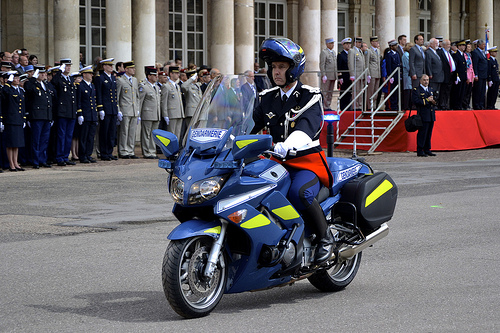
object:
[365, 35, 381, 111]
people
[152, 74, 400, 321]
bike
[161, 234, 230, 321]
wheels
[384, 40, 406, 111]
people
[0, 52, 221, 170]
crowd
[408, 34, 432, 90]
people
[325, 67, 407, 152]
stairs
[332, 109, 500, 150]
stage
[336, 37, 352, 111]
man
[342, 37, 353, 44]
hat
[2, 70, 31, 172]
people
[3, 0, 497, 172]
building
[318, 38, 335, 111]
people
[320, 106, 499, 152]
platform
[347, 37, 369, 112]
people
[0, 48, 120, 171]
military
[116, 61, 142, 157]
men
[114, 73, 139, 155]
suits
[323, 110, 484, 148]
band stand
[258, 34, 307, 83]
helmet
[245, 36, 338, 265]
he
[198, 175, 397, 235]
stripes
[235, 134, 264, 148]
stripes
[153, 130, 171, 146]
stripes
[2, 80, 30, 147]
uniform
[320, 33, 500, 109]
they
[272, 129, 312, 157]
gloves